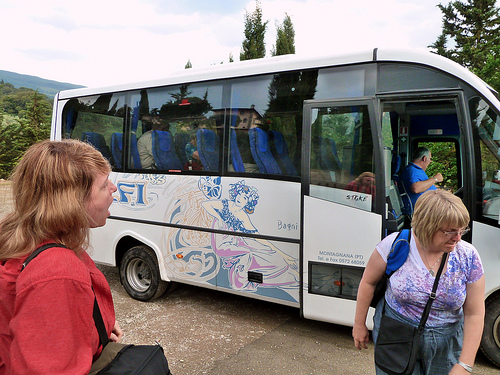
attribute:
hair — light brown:
[8, 131, 102, 254]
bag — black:
[85, 336, 178, 373]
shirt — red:
[7, 235, 114, 374]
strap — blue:
[378, 229, 414, 276]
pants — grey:
[361, 311, 470, 370]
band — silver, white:
[456, 357, 472, 372]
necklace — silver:
[420, 249, 444, 280]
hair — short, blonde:
[407, 179, 473, 234]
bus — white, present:
[40, 37, 489, 328]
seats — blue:
[246, 127, 294, 175]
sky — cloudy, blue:
[14, 8, 232, 64]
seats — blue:
[85, 132, 139, 162]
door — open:
[297, 93, 483, 347]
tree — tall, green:
[238, 6, 269, 61]